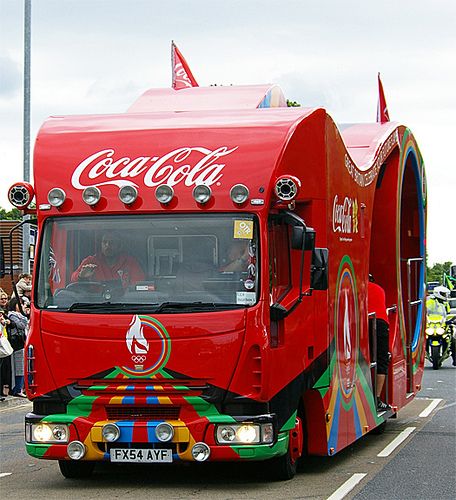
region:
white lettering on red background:
[60, 141, 241, 189]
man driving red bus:
[62, 233, 144, 303]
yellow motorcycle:
[424, 308, 454, 367]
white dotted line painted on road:
[310, 382, 452, 497]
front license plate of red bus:
[110, 445, 175, 465]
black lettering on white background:
[112, 448, 166, 461]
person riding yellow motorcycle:
[428, 285, 450, 309]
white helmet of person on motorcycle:
[429, 282, 453, 301]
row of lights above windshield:
[38, 177, 255, 202]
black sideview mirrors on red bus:
[293, 227, 341, 286]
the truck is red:
[25, 58, 421, 478]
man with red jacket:
[62, 234, 204, 328]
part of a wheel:
[285, 439, 311, 479]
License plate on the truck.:
[105, 439, 175, 475]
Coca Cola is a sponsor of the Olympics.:
[115, 303, 152, 379]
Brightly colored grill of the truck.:
[78, 379, 200, 418]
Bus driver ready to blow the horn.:
[65, 225, 150, 299]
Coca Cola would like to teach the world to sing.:
[69, 141, 250, 192]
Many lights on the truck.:
[40, 174, 255, 211]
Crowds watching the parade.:
[0, 262, 33, 389]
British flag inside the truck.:
[39, 241, 66, 287]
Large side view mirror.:
[303, 236, 334, 290]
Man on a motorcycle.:
[422, 278, 450, 369]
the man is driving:
[68, 222, 182, 321]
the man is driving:
[56, 224, 136, 313]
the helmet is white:
[427, 277, 453, 310]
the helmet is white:
[435, 258, 454, 313]